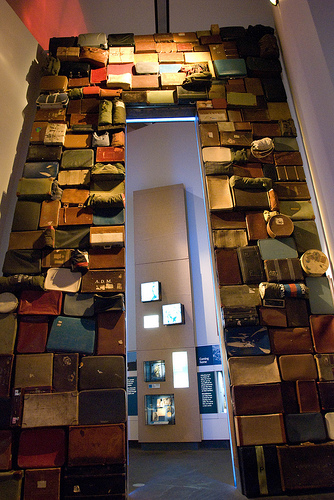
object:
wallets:
[215, 245, 244, 285]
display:
[0, 31, 334, 424]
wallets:
[106, 31, 137, 49]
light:
[94, 40, 206, 80]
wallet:
[48, 34, 81, 56]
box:
[300, 248, 330, 277]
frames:
[131, 185, 201, 495]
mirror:
[126, 114, 232, 424]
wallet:
[139, 280, 163, 306]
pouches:
[0, 424, 15, 472]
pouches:
[21, 461, 65, 500]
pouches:
[0, 314, 18, 357]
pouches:
[16, 426, 67, 470]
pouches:
[15, 315, 49, 356]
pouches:
[13, 352, 53, 391]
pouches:
[0, 290, 19, 315]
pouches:
[20, 391, 79, 430]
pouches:
[18, 286, 62, 318]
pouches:
[0, 352, 14, 402]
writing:
[0, 467, 26, 493]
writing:
[199, 373, 214, 378]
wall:
[313, 0, 333, 217]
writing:
[199, 356, 210, 365]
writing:
[200, 398, 215, 408]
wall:
[127, 122, 190, 178]